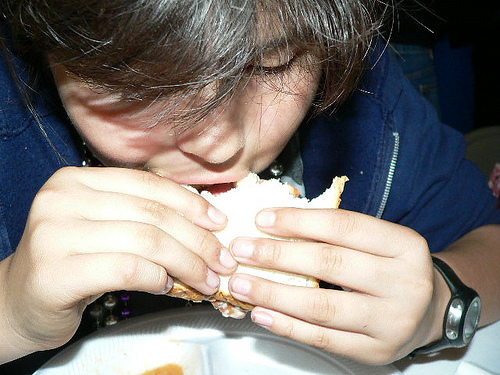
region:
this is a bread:
[230, 200, 254, 225]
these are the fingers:
[267, 224, 375, 349]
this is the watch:
[454, 293, 473, 348]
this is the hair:
[107, 15, 204, 55]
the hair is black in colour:
[127, 12, 200, 47]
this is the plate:
[192, 336, 254, 372]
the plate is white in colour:
[205, 340, 278, 367]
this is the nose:
[195, 142, 245, 163]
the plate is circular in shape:
[162, 337, 245, 361]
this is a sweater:
[356, 94, 446, 210]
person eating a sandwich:
[1, 2, 469, 369]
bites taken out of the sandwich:
[170, 161, 351, 213]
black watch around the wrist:
[413, 254, 486, 366]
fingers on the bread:
[226, 198, 387, 370]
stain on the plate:
[138, 357, 192, 374]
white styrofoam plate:
[28, 295, 397, 372]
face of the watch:
[462, 298, 484, 342]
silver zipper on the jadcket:
[373, 131, 403, 220]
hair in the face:
[46, 3, 383, 132]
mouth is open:
[173, 174, 250, 205]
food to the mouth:
[173, 169, 331, 331]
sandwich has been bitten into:
[261, 166, 341, 201]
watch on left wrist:
[423, 254, 477, 370]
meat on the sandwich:
[211, 293, 254, 327]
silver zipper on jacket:
[374, 129, 400, 224]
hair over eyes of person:
[63, 0, 369, 126]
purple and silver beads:
[91, 293, 133, 333]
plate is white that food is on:
[183, 341, 308, 374]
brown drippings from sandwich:
[143, 367, 190, 374]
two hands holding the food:
[33, 187, 409, 351]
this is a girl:
[6, 8, 359, 133]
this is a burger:
[202, 149, 326, 249]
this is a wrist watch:
[425, 247, 482, 351]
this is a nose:
[175, 115, 240, 164]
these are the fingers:
[67, 175, 189, 284]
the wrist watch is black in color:
[425, 246, 487, 361]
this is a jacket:
[357, 100, 437, 191]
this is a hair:
[103, 0, 233, 94]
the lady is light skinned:
[257, 95, 297, 130]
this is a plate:
[159, 322, 224, 371]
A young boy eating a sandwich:
[21, 5, 441, 366]